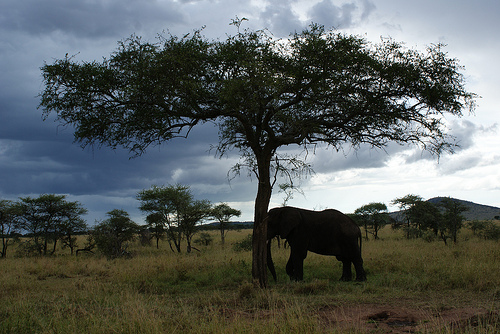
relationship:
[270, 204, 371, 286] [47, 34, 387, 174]
animal near tree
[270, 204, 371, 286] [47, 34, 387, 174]
elephant near tree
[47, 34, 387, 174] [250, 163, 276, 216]
tree has trunk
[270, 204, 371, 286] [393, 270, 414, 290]
elephant in grass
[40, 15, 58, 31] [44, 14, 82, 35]
clouds in sky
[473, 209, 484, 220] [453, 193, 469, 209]
hill in distance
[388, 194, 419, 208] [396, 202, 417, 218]
tree in background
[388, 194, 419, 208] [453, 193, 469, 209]
tree in distance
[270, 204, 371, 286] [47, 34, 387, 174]
elephant rubbing head on tree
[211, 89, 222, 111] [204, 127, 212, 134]
leaf protects from heat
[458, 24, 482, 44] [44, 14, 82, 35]
cloud in sky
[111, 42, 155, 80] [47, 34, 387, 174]
branches are in tree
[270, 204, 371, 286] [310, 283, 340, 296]
elephant touching ground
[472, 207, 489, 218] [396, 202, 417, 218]
mountain in background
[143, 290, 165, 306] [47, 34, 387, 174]
dirt by tree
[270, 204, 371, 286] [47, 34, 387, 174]
elephant by tree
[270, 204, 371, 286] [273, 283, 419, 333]
elephant in field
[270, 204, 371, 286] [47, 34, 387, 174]
elephant next to tre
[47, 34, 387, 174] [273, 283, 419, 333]
tree in a field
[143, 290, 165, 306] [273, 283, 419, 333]
dirt in field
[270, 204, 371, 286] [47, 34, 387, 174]
elephant standing under tree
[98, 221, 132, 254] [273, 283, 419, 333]
bush in field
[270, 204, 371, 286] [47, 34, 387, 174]
elephant next to tree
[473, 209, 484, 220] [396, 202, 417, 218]
hill in background